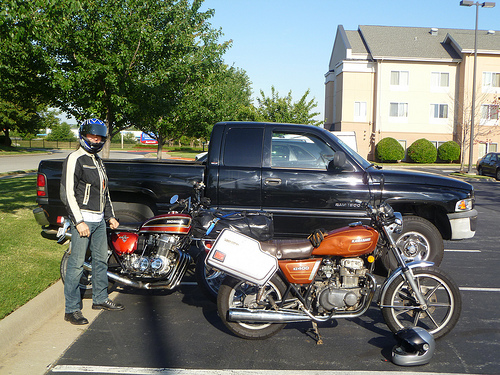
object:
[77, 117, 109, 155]
helmet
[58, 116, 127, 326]
man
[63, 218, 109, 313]
jeans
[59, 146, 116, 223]
jacket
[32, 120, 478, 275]
truck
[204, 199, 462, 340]
bike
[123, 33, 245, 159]
tree